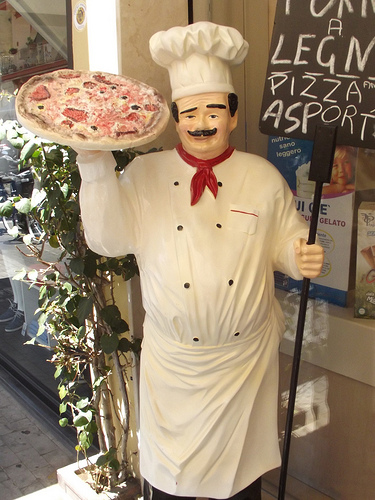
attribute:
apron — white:
[138, 321, 282, 495]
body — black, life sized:
[73, 100, 325, 499]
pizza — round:
[14, 69, 171, 152]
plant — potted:
[0, 120, 133, 483]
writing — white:
[259, 2, 374, 145]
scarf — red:
[175, 144, 235, 206]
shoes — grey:
[1, 301, 26, 335]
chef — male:
[70, 20, 322, 499]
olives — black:
[38, 104, 44, 109]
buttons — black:
[173, 181, 240, 342]